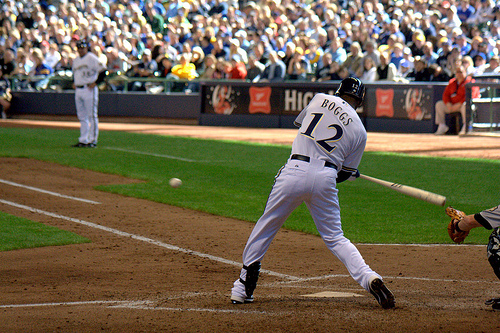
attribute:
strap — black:
[239, 262, 247, 273]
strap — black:
[236, 275, 247, 286]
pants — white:
[75, 85, 103, 147]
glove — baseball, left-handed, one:
[428, 189, 485, 254]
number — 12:
[301, 102, 348, 155]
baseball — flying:
[168, 177, 183, 189]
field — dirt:
[3, 111, 498, 331]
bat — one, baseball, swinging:
[362, 169, 449, 209]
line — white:
[249, 267, 346, 284]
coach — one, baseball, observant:
[69, 37, 109, 149]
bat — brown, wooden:
[358, 170, 451, 206]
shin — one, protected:
[331, 239, 374, 293]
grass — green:
[20, 120, 498, 216]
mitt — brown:
[438, 206, 483, 253]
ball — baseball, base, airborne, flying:
[164, 169, 189, 197]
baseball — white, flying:
[169, 175, 180, 189]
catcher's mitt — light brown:
[444, 206, 469, 243]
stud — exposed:
[390, 298, 392, 301]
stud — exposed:
[391, 302, 394, 305]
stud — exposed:
[380, 298, 383, 300]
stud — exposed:
[380, 280, 382, 283]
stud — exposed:
[373, 285, 376, 288]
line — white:
[107, 301, 300, 316]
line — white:
[353, 239, 484, 247]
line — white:
[1, 295, 131, 308]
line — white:
[106, 299, 282, 317]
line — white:
[1, 195, 301, 279]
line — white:
[1, 177, 101, 204]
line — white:
[262, 272, 338, 289]